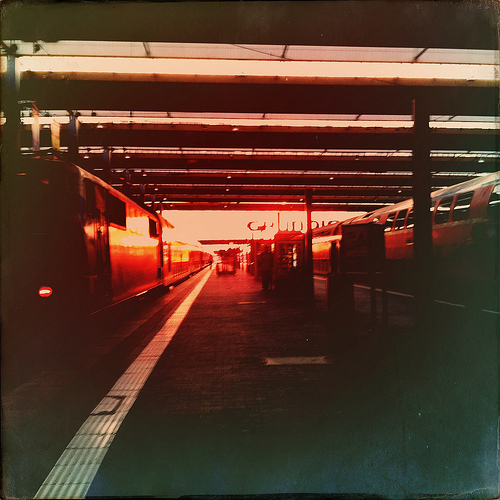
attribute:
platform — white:
[0, 256, 218, 498]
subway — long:
[2, 141, 220, 337]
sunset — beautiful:
[130, 215, 330, 295]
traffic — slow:
[12, 150, 490, 331]